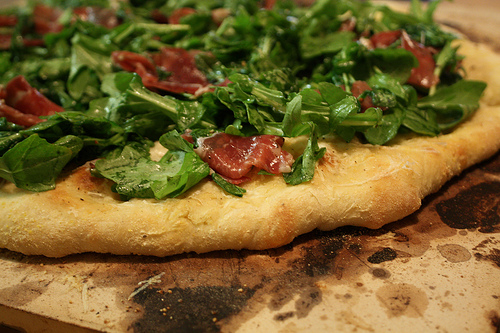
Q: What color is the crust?
A: Brown.